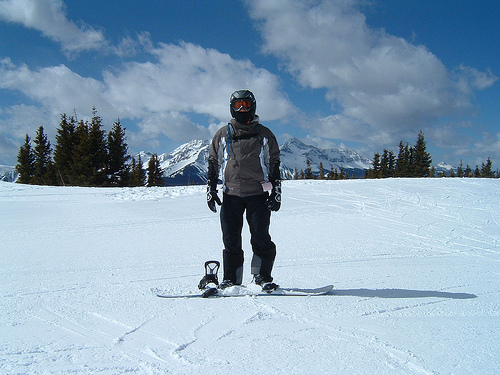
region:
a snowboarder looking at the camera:
[143, 63, 364, 321]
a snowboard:
[136, 253, 353, 320]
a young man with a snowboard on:
[148, 73, 339, 312]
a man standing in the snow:
[156, 64, 311, 336]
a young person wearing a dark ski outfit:
[145, 62, 341, 315]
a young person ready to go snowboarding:
[152, 65, 360, 315]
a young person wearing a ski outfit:
[152, 73, 360, 313]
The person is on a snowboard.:
[151, 82, 336, 302]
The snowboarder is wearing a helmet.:
[152, 83, 343, 305]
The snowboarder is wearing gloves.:
[200, 162, 228, 217]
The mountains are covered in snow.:
[119, 123, 469, 189]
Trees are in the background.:
[366, 131, 441, 177]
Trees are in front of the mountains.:
[14, 99, 161, 186]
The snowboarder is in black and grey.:
[196, 76, 295, 303]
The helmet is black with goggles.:
[228, 88, 260, 123]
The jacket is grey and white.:
[205, 110, 283, 198]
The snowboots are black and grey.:
[248, 243, 288, 291]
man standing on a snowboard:
[153, 87, 334, 299]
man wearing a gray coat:
[203, 85, 287, 295]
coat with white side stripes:
[205, 116, 280, 196]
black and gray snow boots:
[220, 244, 281, 294]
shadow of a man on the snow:
[280, 282, 479, 306]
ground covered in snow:
[0, 175, 497, 374]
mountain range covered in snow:
[0, 133, 472, 181]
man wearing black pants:
[199, 87, 286, 292]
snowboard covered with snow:
[150, 283, 333, 298]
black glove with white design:
[264, 174, 283, 215]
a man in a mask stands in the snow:
[199, 78, 290, 303]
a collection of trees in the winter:
[10, 105, 167, 193]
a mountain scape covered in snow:
[115, 120, 469, 188]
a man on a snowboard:
[143, 64, 338, 308]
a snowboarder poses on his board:
[150, 71, 337, 302]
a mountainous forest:
[0, 115, 495, 182]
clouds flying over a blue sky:
[5, 1, 197, 109]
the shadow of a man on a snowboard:
[162, 267, 480, 315]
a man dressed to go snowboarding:
[203, 81, 284, 292]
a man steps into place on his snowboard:
[152, 74, 334, 305]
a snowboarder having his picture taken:
[156, 71, 366, 313]